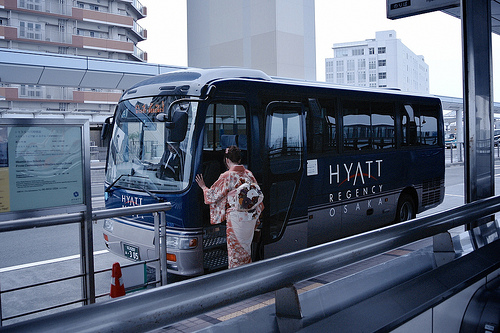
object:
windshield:
[103, 95, 201, 194]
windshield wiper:
[104, 174, 149, 192]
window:
[340, 104, 412, 155]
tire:
[394, 188, 417, 223]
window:
[15, 19, 44, 41]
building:
[0, 0, 159, 115]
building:
[325, 29, 428, 95]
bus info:
[113, 96, 196, 119]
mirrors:
[108, 96, 199, 153]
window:
[100, 96, 198, 192]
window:
[402, 103, 437, 146]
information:
[13, 130, 77, 194]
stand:
[0, 110, 96, 329]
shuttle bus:
[100, 67, 446, 277]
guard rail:
[0, 193, 500, 333]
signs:
[14, 125, 84, 202]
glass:
[0, 123, 86, 222]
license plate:
[123, 243, 141, 262]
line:
[0, 249, 109, 274]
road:
[0, 160, 500, 333]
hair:
[224, 145, 243, 169]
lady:
[195, 145, 266, 269]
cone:
[109, 262, 126, 298]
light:
[167, 253, 177, 262]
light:
[103, 233, 108, 242]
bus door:
[194, 101, 307, 246]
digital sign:
[135, 100, 164, 113]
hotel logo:
[329, 160, 383, 218]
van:
[103, 68, 446, 278]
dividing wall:
[0, 1, 471, 333]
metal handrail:
[0, 201, 173, 329]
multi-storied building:
[187, 0, 316, 82]